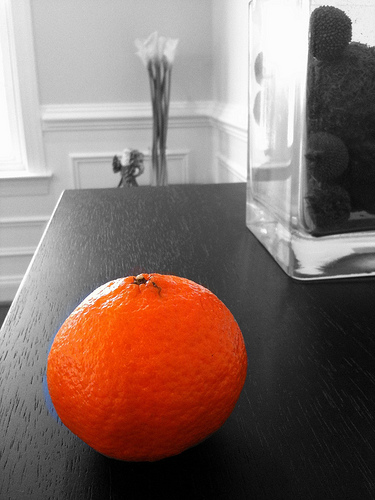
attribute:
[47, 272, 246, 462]
orange — fruit, brown, oval, bumpy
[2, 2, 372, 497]
picture — black, white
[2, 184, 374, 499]
table — black, wood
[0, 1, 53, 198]
window — white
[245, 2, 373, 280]
vase — clear, glass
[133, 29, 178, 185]
flowers — white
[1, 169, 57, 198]
window sill — white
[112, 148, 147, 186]
flower — grey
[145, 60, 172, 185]
stems — long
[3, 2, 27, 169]
curtains — flimsy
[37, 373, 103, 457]
circle — blue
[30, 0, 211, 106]
wallpaper — white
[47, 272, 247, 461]
fruit — round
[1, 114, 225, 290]
panels — white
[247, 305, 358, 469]
pattern — grain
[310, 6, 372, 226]
balls — prickly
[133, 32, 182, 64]
flowers — white